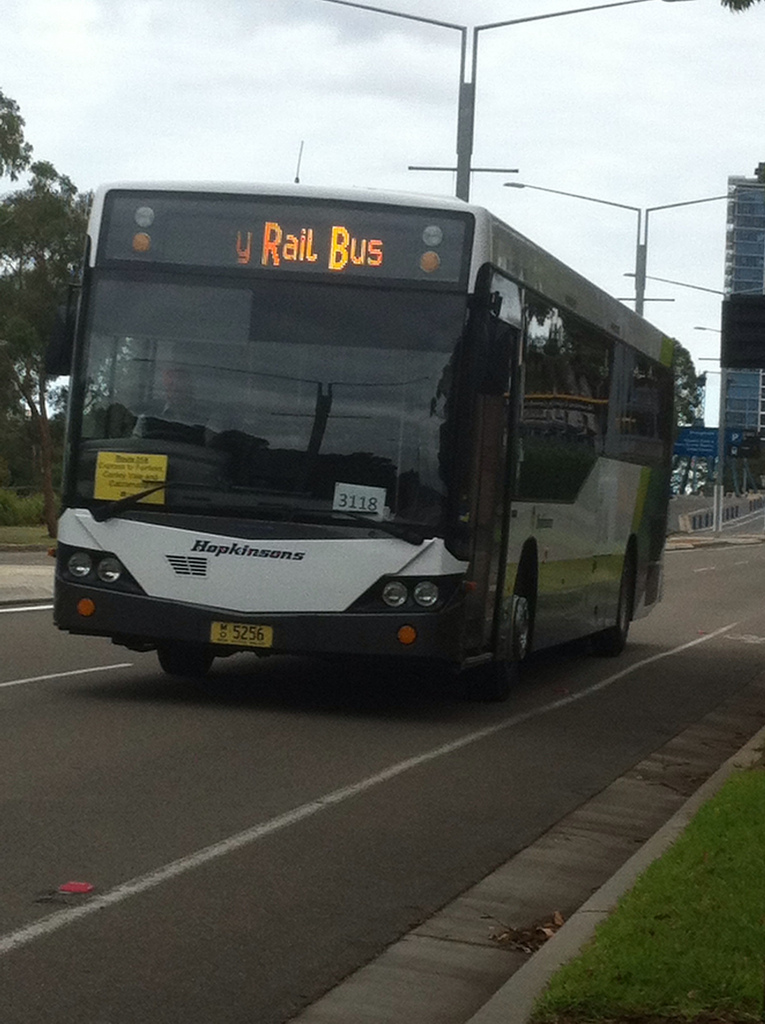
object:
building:
[718, 162, 765, 494]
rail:
[678, 501, 738, 533]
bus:
[55, 137, 674, 701]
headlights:
[68, 551, 121, 583]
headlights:
[383, 581, 439, 608]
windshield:
[69, 265, 467, 530]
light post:
[503, 183, 750, 318]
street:
[0, 492, 765, 1024]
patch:
[617, 917, 765, 1010]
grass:
[521, 762, 765, 1024]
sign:
[673, 427, 719, 455]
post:
[712, 424, 724, 533]